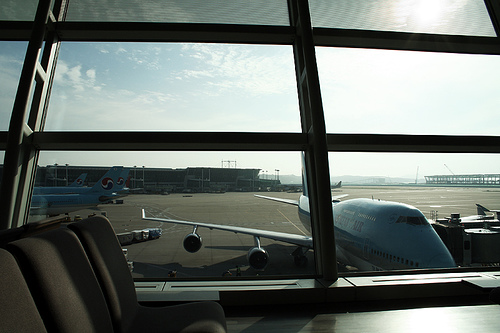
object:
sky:
[1, 1, 500, 180]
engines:
[245, 246, 271, 273]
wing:
[141, 208, 313, 251]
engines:
[181, 232, 203, 254]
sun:
[403, 2, 473, 33]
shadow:
[0, 215, 340, 330]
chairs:
[64, 211, 228, 332]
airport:
[1, 1, 499, 330]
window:
[301, 0, 499, 40]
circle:
[100, 177, 114, 191]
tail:
[89, 165, 127, 197]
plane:
[140, 150, 500, 277]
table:
[134, 290, 220, 303]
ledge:
[38, 130, 500, 154]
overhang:
[431, 213, 499, 265]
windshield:
[406, 215, 423, 227]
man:
[235, 265, 242, 277]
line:
[277, 209, 307, 236]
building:
[0, 163, 282, 192]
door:
[362, 234, 372, 260]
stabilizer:
[288, 244, 312, 268]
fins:
[253, 193, 299, 206]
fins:
[331, 194, 350, 202]